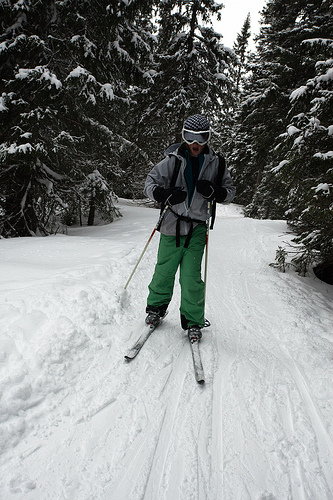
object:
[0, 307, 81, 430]
mound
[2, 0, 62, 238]
tree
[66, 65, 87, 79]
snow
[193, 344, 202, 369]
snow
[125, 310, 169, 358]
skis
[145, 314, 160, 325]
feet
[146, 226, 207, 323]
pants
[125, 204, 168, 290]
pole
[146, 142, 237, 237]
jacket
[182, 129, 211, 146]
goggles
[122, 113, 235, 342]
person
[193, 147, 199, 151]
mouth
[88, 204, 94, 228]
base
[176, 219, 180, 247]
strap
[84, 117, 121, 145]
branches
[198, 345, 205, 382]
edge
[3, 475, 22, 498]
hole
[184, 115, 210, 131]
hat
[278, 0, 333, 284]
trees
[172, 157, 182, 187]
backpack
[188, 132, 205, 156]
face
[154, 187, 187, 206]
hand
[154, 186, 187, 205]
glove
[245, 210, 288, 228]
edge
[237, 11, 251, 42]
top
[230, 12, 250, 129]
tree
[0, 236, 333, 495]
snow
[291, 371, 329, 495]
line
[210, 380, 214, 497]
line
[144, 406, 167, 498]
line